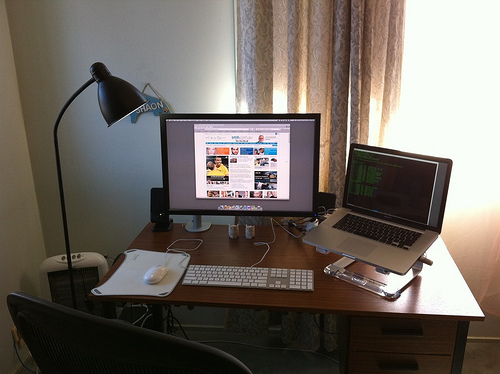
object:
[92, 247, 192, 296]
mouse pad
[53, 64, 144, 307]
lamp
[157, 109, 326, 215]
monitor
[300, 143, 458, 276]
computer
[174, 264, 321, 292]
keyboard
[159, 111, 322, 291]
computer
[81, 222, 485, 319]
desk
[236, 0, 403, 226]
curtain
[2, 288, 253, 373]
chair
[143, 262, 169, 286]
mouse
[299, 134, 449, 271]
laptop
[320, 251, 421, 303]
stand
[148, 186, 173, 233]
speaker